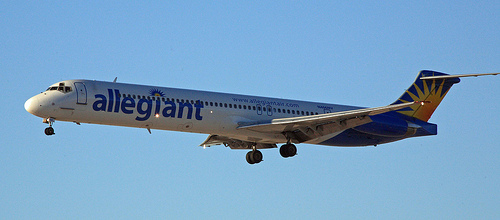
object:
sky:
[0, 0, 500, 220]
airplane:
[22, 69, 500, 165]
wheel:
[250, 150, 264, 163]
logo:
[147, 88, 168, 97]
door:
[74, 81, 88, 104]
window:
[65, 86, 73, 93]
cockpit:
[45, 80, 73, 95]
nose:
[22, 90, 64, 118]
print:
[91, 88, 206, 122]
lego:
[396, 72, 453, 122]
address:
[231, 97, 300, 108]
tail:
[389, 69, 500, 123]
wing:
[236, 100, 432, 145]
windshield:
[46, 82, 73, 94]